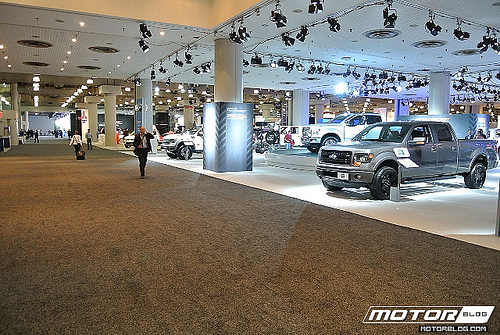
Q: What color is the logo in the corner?
A: White.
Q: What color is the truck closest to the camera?
A: Silver.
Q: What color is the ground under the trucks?
A: White.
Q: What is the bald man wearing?
A: A suit.